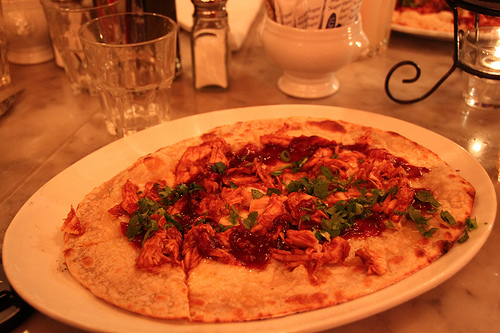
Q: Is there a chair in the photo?
A: No, there are no chairs.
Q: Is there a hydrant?
A: No, there are no fire hydrants.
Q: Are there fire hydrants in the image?
A: No, there are no fire hydrants.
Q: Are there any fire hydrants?
A: No, there are no fire hydrants.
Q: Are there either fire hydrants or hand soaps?
A: No, there are no fire hydrants or hand soaps.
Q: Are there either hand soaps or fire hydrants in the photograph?
A: No, there are no fire hydrants or hand soaps.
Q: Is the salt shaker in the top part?
A: Yes, the salt shaker is in the top of the image.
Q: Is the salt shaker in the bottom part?
A: No, the salt shaker is in the top of the image.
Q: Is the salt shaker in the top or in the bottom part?
A: The salt shaker is in the top of the image.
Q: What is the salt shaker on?
A: The salt shaker is on the table.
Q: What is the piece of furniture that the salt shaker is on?
A: The piece of furniture is a table.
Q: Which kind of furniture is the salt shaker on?
A: The salt shaker is on the table.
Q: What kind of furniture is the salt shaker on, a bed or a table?
A: The salt shaker is on a table.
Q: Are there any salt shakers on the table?
A: Yes, there is a salt shaker on the table.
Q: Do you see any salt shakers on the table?
A: Yes, there is a salt shaker on the table.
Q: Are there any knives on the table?
A: No, there is a salt shaker on the table.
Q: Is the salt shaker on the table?
A: Yes, the salt shaker is on the table.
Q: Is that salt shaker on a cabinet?
A: No, the salt shaker is on the table.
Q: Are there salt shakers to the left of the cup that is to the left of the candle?
A: Yes, there is a salt shaker to the left of the cup.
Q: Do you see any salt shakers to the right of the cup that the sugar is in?
A: No, the salt shaker is to the left of the cup.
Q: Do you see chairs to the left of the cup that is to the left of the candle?
A: No, there is a salt shaker to the left of the cup.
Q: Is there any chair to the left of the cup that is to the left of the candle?
A: No, there is a salt shaker to the left of the cup.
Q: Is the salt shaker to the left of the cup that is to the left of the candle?
A: Yes, the salt shaker is to the left of the cup.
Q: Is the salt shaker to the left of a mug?
A: No, the salt shaker is to the left of the cup.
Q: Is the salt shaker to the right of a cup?
A: No, the salt shaker is to the left of a cup.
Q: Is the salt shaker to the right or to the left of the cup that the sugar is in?
A: The salt shaker is to the left of the cup.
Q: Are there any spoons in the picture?
A: No, there are no spoons.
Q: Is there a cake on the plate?
A: No, there is a vegetable on the plate.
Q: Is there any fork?
A: No, there are no forks.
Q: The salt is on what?
A: The salt is on the table.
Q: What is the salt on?
A: The salt is on the table.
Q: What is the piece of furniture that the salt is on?
A: The piece of furniture is a table.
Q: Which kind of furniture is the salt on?
A: The salt is on the table.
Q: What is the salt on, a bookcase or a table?
A: The salt is on a table.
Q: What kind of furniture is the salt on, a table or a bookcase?
A: The salt is on a table.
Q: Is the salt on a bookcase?
A: No, the salt is on the table.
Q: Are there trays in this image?
A: No, there are no trays.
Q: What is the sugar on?
A: The sugar is on the table.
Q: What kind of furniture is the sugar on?
A: The sugar is on the table.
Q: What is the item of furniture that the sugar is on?
A: The piece of furniture is a table.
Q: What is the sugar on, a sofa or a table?
A: The sugar is on a table.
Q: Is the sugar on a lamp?
A: No, the sugar is on the table.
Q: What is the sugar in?
A: The sugar is in the cup.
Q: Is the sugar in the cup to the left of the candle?
A: Yes, the sugar is in the cup.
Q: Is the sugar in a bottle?
A: No, the sugar is in the cup.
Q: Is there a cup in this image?
A: Yes, there is a cup.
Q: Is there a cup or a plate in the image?
A: Yes, there is a cup.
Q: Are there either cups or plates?
A: Yes, there is a cup.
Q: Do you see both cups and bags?
A: No, there is a cup but no bags.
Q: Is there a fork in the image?
A: No, there are no forks.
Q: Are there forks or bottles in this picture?
A: No, there are no forks or bottles.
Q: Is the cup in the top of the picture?
A: Yes, the cup is in the top of the image.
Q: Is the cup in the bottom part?
A: No, the cup is in the top of the image.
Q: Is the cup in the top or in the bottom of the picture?
A: The cup is in the top of the image.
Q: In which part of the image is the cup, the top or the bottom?
A: The cup is in the top of the image.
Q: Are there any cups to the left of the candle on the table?
A: Yes, there is a cup to the left of the candle.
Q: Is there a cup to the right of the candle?
A: No, the cup is to the left of the candle.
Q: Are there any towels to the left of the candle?
A: No, there is a cup to the left of the candle.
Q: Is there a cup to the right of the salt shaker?
A: Yes, there is a cup to the right of the salt shaker.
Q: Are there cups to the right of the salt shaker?
A: Yes, there is a cup to the right of the salt shaker.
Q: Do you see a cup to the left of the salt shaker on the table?
A: No, the cup is to the right of the salt shaker.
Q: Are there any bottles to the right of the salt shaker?
A: No, there is a cup to the right of the salt shaker.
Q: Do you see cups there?
A: Yes, there is a cup.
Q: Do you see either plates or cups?
A: Yes, there is a cup.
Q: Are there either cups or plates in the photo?
A: Yes, there is a cup.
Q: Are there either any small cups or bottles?
A: Yes, there is a small cup.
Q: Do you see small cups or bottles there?
A: Yes, there is a small cup.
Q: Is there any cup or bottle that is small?
A: Yes, the cup is small.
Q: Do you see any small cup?
A: Yes, there is a small cup.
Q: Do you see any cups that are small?
A: Yes, there is a small cup.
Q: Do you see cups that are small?
A: Yes, there is a cup that is small.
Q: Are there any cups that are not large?
A: Yes, there is a small cup.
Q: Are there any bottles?
A: No, there are no bottles.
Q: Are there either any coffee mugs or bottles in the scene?
A: No, there are no bottles or coffee mugs.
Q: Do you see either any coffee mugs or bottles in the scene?
A: No, there are no bottles or coffee mugs.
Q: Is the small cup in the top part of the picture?
A: Yes, the cup is in the top of the image.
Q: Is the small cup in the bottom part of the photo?
A: No, the cup is in the top of the image.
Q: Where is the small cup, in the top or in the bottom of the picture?
A: The cup is in the top of the image.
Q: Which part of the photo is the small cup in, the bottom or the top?
A: The cup is in the top of the image.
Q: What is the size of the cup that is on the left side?
A: The cup is small.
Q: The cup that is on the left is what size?
A: The cup is small.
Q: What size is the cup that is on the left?
A: The cup is small.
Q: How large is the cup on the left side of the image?
A: The cup is small.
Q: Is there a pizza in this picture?
A: Yes, there is a pizza.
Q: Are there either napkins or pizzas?
A: Yes, there is a pizza.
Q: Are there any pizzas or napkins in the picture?
A: Yes, there is a pizza.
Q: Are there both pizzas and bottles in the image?
A: No, there is a pizza but no bottles.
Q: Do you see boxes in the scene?
A: No, there are no boxes.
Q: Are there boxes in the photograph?
A: No, there are no boxes.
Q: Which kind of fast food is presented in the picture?
A: The fast food is a pizza.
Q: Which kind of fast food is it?
A: The food is a pizza.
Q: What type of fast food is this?
A: This is a pizza.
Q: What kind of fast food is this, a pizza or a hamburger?
A: This is a pizza.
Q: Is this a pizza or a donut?
A: This is a pizza.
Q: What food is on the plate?
A: The food is a pizza.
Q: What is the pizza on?
A: The pizza is on the plate.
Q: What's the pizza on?
A: The pizza is on the plate.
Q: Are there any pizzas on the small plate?
A: Yes, there is a pizza on the plate.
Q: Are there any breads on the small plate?
A: No, there is a pizza on the plate.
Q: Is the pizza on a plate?
A: Yes, the pizza is on a plate.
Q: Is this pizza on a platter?
A: No, the pizza is on a plate.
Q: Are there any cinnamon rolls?
A: No, there are no cinnamon rolls.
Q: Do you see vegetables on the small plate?
A: Yes, there is a vegetable on the plate.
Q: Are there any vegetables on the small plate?
A: Yes, there is a vegetable on the plate.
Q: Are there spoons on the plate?
A: No, there is a vegetable on the plate.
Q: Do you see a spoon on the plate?
A: No, there is a vegetable on the plate.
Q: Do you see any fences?
A: No, there are no fences.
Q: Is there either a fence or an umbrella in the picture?
A: No, there are no fences or umbrellas.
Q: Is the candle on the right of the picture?
A: Yes, the candle is on the right of the image.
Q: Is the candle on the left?
A: No, the candle is on the right of the image.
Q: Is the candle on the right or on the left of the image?
A: The candle is on the right of the image.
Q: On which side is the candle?
A: The candle is on the right of the image.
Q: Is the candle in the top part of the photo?
A: Yes, the candle is in the top of the image.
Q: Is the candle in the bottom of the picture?
A: No, the candle is in the top of the image.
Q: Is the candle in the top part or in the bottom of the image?
A: The candle is in the top of the image.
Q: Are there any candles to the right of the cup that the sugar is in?
A: Yes, there is a candle to the right of the cup.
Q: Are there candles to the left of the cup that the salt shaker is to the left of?
A: No, the candle is to the right of the cup.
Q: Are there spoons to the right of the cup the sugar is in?
A: No, there is a candle to the right of the cup.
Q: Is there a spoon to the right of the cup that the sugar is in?
A: No, there is a candle to the right of the cup.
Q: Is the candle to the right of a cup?
A: Yes, the candle is to the right of a cup.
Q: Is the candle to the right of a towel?
A: No, the candle is to the right of a cup.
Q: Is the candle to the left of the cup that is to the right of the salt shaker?
A: No, the candle is to the right of the cup.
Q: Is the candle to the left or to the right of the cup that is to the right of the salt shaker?
A: The candle is to the right of the cup.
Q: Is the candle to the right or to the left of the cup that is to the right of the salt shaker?
A: The candle is to the right of the cup.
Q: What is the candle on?
A: The candle is on the table.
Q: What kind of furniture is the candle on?
A: The candle is on the table.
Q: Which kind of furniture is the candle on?
A: The candle is on the table.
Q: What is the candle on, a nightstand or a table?
A: The candle is on a table.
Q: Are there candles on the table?
A: Yes, there is a candle on the table.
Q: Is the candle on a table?
A: Yes, the candle is on a table.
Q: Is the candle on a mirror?
A: No, the candle is on a table.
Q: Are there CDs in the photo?
A: No, there are no cds.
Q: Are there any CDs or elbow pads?
A: No, there are no CDs or elbow pads.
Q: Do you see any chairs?
A: No, there are no chairs.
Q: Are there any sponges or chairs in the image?
A: No, there are no chairs or sponges.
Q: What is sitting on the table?
A: The glass is sitting on the table.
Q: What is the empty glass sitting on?
A: The glass is sitting on the table.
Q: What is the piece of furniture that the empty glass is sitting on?
A: The piece of furniture is a table.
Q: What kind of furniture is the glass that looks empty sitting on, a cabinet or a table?
A: The glass is sitting on a table.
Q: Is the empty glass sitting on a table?
A: Yes, the glass is sitting on a table.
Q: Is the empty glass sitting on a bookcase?
A: No, the glass is sitting on a table.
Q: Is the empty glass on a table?
A: Yes, the glass is on a table.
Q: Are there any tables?
A: Yes, there is a table.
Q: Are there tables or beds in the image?
A: Yes, there is a table.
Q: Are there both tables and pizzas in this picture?
A: Yes, there are both a table and a pizza.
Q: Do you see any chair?
A: No, there are no chairs.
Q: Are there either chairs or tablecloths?
A: No, there are no chairs or tablecloths.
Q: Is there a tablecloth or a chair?
A: No, there are no chairs or tablecloths.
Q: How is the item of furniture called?
A: The piece of furniture is a table.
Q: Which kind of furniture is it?
A: The piece of furniture is a table.